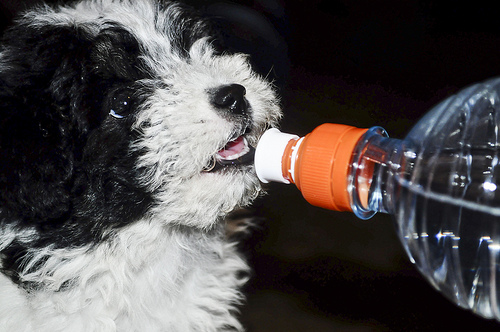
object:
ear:
[2, 43, 92, 227]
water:
[411, 119, 500, 263]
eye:
[94, 73, 148, 123]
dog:
[3, 3, 293, 330]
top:
[251, 121, 373, 211]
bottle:
[249, 75, 498, 325]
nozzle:
[253, 125, 299, 185]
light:
[399, 148, 419, 161]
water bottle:
[253, 77, 500, 320]